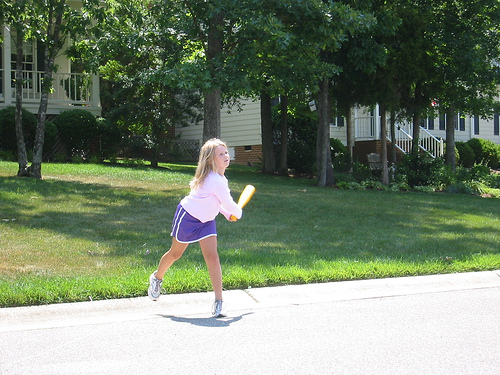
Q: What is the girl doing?
A: Swinging a bat.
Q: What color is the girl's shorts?
A: Blue and white.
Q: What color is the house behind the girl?
A: White.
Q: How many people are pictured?
A: One.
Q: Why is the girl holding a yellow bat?
A: To play.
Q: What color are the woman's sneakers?
A: White.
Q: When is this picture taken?
A: Afternoon.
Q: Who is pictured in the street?
A: Young girl.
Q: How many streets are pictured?
A: One.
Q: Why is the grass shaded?
A: Under a tree.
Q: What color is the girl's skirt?
A: Purple.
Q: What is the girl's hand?
A: A bat.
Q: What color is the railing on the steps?
A: White.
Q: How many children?
A: 1.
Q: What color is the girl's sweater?
A: Pink.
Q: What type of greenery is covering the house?
A: Trees and bushes.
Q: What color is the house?
A: White.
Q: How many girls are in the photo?
A: One.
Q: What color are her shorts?
A: Purple.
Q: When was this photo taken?
A: Daytime.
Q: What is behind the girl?
A: Houses.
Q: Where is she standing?
A: On the sidewalk.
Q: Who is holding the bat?
A: The girl.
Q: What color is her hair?
A: Blonde.